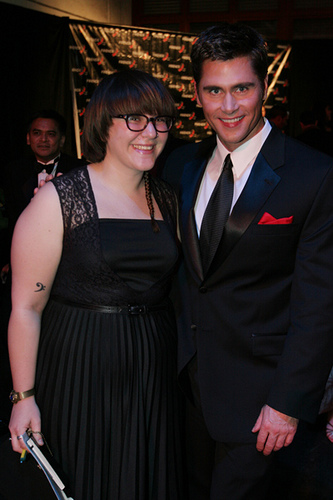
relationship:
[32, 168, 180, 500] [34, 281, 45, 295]
woman with tattoo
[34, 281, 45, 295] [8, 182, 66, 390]
tattoo on arm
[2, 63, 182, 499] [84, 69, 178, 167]
woman has short hair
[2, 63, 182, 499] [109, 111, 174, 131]
woman wears glasses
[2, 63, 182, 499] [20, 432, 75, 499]
woman holds notebook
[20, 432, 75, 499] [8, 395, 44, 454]
notebook in hand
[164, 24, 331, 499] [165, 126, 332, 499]
man wears black suit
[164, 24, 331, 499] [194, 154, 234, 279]
man wearing tie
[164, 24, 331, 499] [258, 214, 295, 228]
man has handkerchief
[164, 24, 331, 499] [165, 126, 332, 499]
man wearing black suit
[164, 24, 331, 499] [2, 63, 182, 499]
man standing behind woman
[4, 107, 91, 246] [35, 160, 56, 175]
man wearing bowtie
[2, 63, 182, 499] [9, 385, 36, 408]
woman has bracelet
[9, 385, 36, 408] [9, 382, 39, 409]
bracelet on wrist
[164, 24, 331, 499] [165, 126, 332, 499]
man in black suit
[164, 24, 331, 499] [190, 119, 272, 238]
man has white shirt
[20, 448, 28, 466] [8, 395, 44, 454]
pen in hand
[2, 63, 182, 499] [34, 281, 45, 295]
woman has tattoo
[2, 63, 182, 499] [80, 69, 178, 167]
woman has short hair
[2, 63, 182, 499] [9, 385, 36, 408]
woman wears watch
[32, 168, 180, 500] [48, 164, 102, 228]
dress has black lace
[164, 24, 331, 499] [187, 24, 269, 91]
man with hair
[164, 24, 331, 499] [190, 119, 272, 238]
man wearing white shirt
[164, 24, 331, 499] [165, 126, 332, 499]
man wears suit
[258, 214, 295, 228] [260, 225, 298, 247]
handkerchief in pocket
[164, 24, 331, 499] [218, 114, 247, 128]
man has lips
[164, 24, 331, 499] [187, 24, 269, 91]
man has hair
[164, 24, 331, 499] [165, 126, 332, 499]
man in suit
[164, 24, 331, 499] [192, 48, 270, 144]
man has face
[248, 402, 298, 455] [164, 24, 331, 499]
left hand of man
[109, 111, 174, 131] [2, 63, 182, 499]
glasses on woman